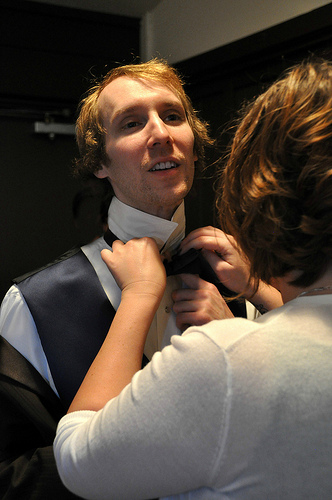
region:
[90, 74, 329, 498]
A woman fixing a man's tie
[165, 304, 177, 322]
A round brown button on shirt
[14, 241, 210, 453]
A black shiny vest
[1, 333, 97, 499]
A black jacket hanging off shoulder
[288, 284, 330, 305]
A silver necklace worn by woman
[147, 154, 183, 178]
White teeth in man's mouth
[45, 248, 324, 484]
woman wears a white shirt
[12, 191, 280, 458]
Man wears white shirt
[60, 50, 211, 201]
Man has brown hair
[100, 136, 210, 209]
Man has stubble on his face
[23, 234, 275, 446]
a black formal vest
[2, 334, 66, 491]
some black on black pinstriped cloth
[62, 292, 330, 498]
a thin white shirt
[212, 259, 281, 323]
a tattoo on a wrist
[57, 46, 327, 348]
a woman tying a man's bowtie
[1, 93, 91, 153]
a hinge on a door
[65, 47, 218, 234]
a blonde long haired man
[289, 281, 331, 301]
a thin silver necklace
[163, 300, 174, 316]
a small round button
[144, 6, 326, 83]
a dark colored door frame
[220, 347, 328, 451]
Lady is wearing a white shirt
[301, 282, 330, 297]
lady is wearing a necklace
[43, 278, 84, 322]
Man is wearing a blue vest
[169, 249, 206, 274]
Lady is helping with tie.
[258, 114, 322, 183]
Lady has brown hair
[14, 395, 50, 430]
Man has on black suit jacket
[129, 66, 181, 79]
man has blonde hair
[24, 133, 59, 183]
Door in the background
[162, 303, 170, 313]
Buttons on mans shirt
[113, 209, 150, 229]
man is wearing white collar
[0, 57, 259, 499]
white man who can't tie his tie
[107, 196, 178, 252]
pointy white right side shirt collar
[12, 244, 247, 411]
shiny black formal vest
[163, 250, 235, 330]
the man's left hand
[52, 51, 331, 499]
woman in white shirt tying a black tie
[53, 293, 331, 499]
left sleeve of white shirt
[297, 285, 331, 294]
silver metal necklace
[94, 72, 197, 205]
prominent cheekbones on the man's face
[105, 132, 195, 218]
bristly five o'clock shadow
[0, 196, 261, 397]
white men's formal dress shirt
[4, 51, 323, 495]
woman adjusting the bowtie of a man in a suit and vest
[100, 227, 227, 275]
black bow tie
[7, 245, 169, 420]
black satin vest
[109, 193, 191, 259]
white lapels of collared shirt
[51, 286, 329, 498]
white cotten quarter length sleeve sweater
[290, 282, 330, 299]
silver necklace on woman's neck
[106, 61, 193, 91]
patch of blonde hair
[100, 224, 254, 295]
two hands adjusting bowtie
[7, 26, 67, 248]
wall with black paint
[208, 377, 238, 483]
arm seam in white sweater